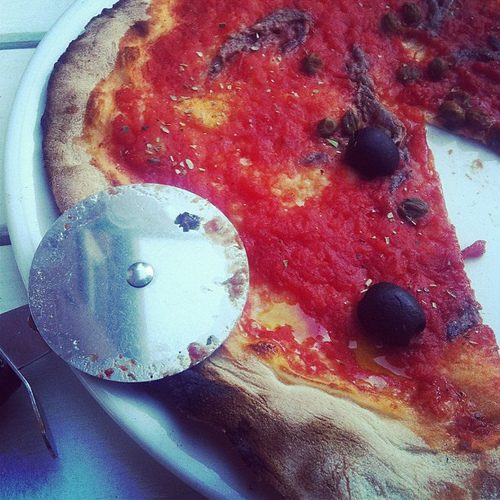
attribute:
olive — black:
[348, 275, 427, 400]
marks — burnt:
[316, 113, 427, 195]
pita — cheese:
[35, 23, 491, 479]